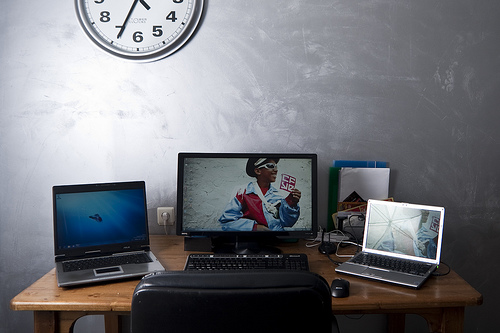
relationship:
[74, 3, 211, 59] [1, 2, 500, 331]
clock on wall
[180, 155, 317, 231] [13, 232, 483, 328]
computer on desk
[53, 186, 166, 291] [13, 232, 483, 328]
laptop on desk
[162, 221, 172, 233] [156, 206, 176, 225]
power cord in electric socket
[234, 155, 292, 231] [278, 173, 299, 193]
man holding sign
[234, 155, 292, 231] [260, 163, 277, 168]
man wearing sunglasses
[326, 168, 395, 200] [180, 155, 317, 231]
papers next to computer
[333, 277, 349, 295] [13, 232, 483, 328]
mouse on desk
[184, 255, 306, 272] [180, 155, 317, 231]
keyboard next to computer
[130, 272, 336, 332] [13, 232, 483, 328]
chair in front of desk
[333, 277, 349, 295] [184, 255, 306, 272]
mouse and keyboard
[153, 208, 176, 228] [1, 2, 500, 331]
electric socket on wall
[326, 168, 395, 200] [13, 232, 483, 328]
papers on desk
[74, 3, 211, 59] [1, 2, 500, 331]
clock hanging on wall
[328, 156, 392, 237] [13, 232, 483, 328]
file on desk